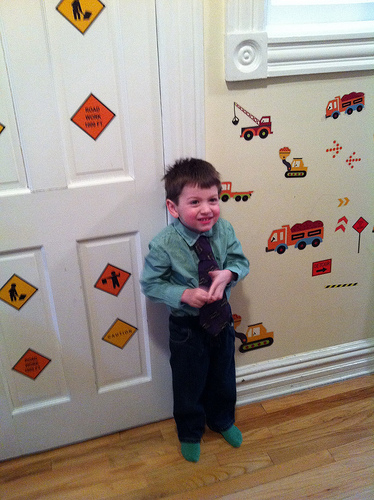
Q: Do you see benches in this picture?
A: No, there are no benches.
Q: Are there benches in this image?
A: No, there are no benches.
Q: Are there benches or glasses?
A: No, there are no benches or glasses.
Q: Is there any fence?
A: No, there are no fences.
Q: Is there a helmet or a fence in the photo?
A: No, there are no fences or helmets.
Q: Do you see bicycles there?
A: No, there are no bicycles.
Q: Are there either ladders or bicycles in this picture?
A: No, there are no bicycles or ladders.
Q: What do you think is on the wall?
A: The sticker is on the wall.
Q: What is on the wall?
A: The sticker is on the wall.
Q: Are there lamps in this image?
A: No, there are no lamps.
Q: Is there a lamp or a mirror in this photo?
A: No, there are no lamps or mirrors.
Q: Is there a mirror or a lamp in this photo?
A: No, there are no lamps or mirrors.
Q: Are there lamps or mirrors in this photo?
A: No, there are no lamps or mirrors.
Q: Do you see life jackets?
A: No, there are no life jackets.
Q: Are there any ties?
A: Yes, there is a tie.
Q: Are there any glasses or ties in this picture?
A: Yes, there is a tie.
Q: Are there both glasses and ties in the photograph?
A: No, there is a tie but no glasses.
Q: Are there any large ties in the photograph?
A: Yes, there is a large tie.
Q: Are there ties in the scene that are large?
A: Yes, there is a tie that is large.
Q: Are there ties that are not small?
A: Yes, there is a large tie.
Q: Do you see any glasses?
A: No, there are no glasses.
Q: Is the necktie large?
A: Yes, the necktie is large.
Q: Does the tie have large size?
A: Yes, the tie is large.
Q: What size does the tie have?
A: The tie has large size.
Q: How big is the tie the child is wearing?
A: The necktie is large.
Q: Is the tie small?
A: No, the tie is large.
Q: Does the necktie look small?
A: No, the necktie is large.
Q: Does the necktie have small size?
A: No, the necktie is large.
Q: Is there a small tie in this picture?
A: No, there is a tie but it is large.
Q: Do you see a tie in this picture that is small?
A: No, there is a tie but it is large.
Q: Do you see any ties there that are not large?
A: No, there is a tie but it is large.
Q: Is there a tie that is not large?
A: No, there is a tie but it is large.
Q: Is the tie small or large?
A: The tie is large.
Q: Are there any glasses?
A: No, there are no glasses.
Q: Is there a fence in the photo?
A: No, there are no fences.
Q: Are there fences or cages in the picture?
A: No, there are no fences or cages.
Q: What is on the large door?
A: The sticker is on the door.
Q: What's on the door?
A: The sticker is on the door.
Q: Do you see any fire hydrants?
A: No, there are no fire hydrants.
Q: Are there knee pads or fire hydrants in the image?
A: No, there are no fire hydrants or knee pads.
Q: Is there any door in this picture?
A: Yes, there is a door.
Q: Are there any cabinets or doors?
A: Yes, there is a door.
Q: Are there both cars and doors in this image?
A: No, there is a door but no cars.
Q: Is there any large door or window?
A: Yes, there is a large door.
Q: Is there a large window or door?
A: Yes, there is a large door.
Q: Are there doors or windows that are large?
A: Yes, the door is large.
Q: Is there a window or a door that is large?
A: Yes, the door is large.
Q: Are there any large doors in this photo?
A: Yes, there is a large door.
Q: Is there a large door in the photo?
A: Yes, there is a large door.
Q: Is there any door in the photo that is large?
A: Yes, there is a door that is large.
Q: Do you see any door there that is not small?
A: Yes, there is a large door.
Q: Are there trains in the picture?
A: No, there are no trains.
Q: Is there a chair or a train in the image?
A: No, there are no trains or chairs.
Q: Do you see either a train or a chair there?
A: No, there are no trains or chairs.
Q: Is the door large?
A: Yes, the door is large.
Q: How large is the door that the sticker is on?
A: The door is large.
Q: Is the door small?
A: No, the door is large.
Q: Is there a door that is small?
A: No, there is a door but it is large.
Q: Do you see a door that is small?
A: No, there is a door but it is large.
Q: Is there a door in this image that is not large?
A: No, there is a door but it is large.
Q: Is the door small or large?
A: The door is large.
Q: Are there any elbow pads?
A: No, there are no elbow pads.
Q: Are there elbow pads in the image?
A: No, there are no elbow pads.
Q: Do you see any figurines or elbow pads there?
A: No, there are no elbow pads or figurines.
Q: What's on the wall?
A: The sticker is on the wall.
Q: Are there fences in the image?
A: No, there are no fences.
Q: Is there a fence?
A: No, there are no fences.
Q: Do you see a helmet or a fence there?
A: No, there are no fences or helmets.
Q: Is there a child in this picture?
A: Yes, there is a child.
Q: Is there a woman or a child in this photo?
A: Yes, there is a child.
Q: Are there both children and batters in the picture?
A: No, there is a child but no batters.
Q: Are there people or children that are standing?
A: Yes, the child is standing.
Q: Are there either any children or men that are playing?
A: Yes, the child is playing.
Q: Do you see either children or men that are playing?
A: Yes, the child is playing.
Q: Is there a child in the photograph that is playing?
A: Yes, there is a child that is playing.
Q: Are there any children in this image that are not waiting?
A: Yes, there is a child that is playing.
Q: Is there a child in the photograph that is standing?
A: Yes, there is a child that is standing.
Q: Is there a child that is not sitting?
A: Yes, there is a child that is standing.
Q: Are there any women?
A: No, there are no women.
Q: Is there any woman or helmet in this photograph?
A: No, there are no women or helmets.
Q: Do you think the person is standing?
A: Yes, the kid is standing.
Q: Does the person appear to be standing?
A: Yes, the child is standing.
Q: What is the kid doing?
A: The kid is standing.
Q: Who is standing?
A: The kid is standing.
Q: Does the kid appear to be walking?
A: No, the kid is standing.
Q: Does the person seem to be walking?
A: No, the kid is standing.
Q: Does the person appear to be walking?
A: No, the kid is standing.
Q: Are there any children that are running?
A: No, there is a child but he is standing.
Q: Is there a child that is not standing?
A: No, there is a child but he is standing.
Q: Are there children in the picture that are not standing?
A: No, there is a child but he is standing.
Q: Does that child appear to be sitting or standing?
A: The child is standing.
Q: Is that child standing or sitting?
A: The child is standing.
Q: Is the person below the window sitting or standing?
A: The child is standing.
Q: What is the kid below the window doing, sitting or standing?
A: The child is standing.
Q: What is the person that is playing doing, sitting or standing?
A: The child is standing.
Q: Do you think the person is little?
A: Yes, the kid is little.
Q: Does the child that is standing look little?
A: Yes, the child is little.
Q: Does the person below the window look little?
A: Yes, the child is little.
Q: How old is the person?
A: The kid is little.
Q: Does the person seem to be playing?
A: Yes, the child is playing.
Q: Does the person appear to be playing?
A: Yes, the child is playing.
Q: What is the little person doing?
A: The child is playing.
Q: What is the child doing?
A: The child is playing.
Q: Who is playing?
A: The kid is playing.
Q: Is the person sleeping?
A: No, the kid is playing.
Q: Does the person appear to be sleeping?
A: No, the kid is playing.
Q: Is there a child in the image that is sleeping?
A: No, there is a child but he is playing.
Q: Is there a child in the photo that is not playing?
A: No, there is a child but he is playing.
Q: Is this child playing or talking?
A: The child is playing.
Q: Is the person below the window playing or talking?
A: The child is playing.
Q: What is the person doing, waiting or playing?
A: The kid is playing.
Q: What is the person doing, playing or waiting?
A: The kid is playing.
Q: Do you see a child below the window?
A: Yes, there is a child below the window.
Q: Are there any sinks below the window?
A: No, there is a child below the window.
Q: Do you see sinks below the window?
A: No, there is a child below the window.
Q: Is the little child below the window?
A: Yes, the kid is below the window.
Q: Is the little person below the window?
A: Yes, the kid is below the window.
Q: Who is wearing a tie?
A: The kid is wearing a tie.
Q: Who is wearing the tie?
A: The kid is wearing a tie.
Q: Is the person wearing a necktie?
A: Yes, the kid is wearing a necktie.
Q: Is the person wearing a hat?
A: No, the kid is wearing a necktie.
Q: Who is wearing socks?
A: The kid is wearing socks.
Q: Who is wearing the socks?
A: The kid is wearing socks.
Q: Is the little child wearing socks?
A: Yes, the kid is wearing socks.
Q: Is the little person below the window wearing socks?
A: Yes, the kid is wearing socks.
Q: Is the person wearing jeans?
A: No, the kid is wearing socks.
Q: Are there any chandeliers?
A: No, there are no chandeliers.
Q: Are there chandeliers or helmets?
A: No, there are no chandeliers or helmets.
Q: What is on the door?
A: The sticker is on the door.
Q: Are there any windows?
A: Yes, there is a window.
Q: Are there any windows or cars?
A: Yes, there is a window.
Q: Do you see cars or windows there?
A: Yes, there is a window.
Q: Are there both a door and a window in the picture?
A: Yes, there are both a window and a door.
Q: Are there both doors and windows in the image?
A: Yes, there are both a window and a door.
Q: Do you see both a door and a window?
A: Yes, there are both a window and a door.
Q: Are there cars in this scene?
A: No, there are no cars.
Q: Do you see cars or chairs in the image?
A: No, there are no cars or chairs.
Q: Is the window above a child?
A: Yes, the window is above a child.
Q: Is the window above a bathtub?
A: No, the window is above a child.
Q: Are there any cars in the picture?
A: No, there are no cars.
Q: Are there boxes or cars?
A: No, there are no cars or boxes.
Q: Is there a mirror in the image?
A: No, there are no mirrors.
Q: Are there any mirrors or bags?
A: No, there are no mirrors or bags.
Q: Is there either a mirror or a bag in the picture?
A: No, there are no mirrors or bags.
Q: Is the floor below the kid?
A: Yes, the floor is below the kid.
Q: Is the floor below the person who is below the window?
A: Yes, the floor is below the kid.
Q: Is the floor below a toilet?
A: No, the floor is below the kid.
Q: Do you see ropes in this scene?
A: No, there are no ropes.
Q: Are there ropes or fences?
A: No, there are no ropes or fences.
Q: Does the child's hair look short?
A: Yes, the hair is short.